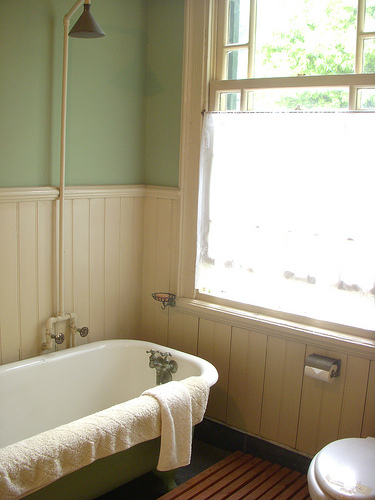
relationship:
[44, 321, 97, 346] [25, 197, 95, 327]
knobs are connected to pipe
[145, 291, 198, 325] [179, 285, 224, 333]
dish connected to sill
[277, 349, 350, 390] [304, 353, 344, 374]
paper on holder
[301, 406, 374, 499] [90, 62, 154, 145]
toilet next to wall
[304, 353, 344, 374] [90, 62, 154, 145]
holder on wall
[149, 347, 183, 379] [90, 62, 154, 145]
faucets on wall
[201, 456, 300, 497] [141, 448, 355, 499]
pallet on floor